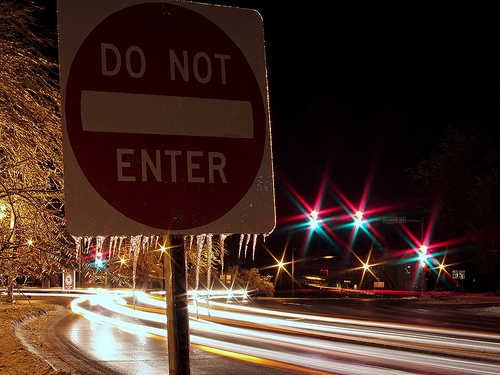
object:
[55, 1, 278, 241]
sign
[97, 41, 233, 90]
text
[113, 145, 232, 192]
text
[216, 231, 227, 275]
icicle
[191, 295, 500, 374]
road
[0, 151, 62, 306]
tree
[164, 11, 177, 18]
circle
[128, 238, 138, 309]
icicle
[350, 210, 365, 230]
light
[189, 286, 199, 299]
headlight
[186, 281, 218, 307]
car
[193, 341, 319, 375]
line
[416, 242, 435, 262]
light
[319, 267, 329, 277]
window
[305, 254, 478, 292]
building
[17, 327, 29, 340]
snow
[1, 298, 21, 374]
ground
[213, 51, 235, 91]
letter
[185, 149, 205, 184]
text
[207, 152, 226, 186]
letter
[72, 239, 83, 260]
icicle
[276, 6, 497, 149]
sky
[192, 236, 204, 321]
icicle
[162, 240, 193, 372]
pole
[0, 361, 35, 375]
grass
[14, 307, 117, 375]
curb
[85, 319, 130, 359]
reflection